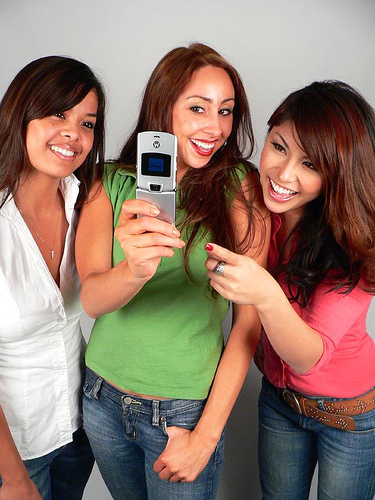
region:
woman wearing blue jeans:
[279, 91, 369, 487]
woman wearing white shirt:
[5, 49, 81, 430]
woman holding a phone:
[105, 45, 233, 432]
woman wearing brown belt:
[276, 87, 368, 495]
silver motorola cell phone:
[133, 131, 185, 225]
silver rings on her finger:
[212, 258, 227, 274]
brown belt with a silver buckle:
[271, 392, 373, 424]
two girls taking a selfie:
[80, 44, 368, 309]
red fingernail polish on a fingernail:
[200, 243, 214, 251]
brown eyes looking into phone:
[190, 100, 239, 119]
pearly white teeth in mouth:
[263, 172, 294, 199]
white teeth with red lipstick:
[42, 137, 83, 160]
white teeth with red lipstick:
[187, 131, 227, 159]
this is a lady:
[243, 72, 373, 498]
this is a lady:
[78, 43, 278, 496]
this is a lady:
[0, 52, 107, 494]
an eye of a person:
[262, 132, 292, 163]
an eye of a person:
[298, 148, 324, 186]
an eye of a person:
[208, 89, 246, 128]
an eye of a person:
[185, 99, 211, 120]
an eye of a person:
[79, 114, 98, 133]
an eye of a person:
[47, 102, 75, 129]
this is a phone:
[115, 122, 201, 279]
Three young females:
[2, 28, 373, 477]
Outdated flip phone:
[130, 123, 177, 226]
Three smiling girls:
[2, 18, 373, 254]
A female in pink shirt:
[202, 68, 372, 415]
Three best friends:
[0, 30, 371, 341]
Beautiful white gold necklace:
[2, 173, 74, 272]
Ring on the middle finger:
[200, 237, 260, 306]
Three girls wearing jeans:
[0, 40, 370, 491]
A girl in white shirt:
[0, 46, 122, 474]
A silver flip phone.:
[137, 130, 178, 226]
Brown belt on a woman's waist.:
[262, 376, 374, 430]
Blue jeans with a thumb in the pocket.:
[79, 365, 225, 498]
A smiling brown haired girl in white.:
[0, 54, 103, 499]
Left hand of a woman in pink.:
[202, 241, 264, 303]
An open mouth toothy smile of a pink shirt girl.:
[266, 175, 299, 202]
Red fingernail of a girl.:
[203, 244, 213, 250]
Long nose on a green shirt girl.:
[203, 108, 222, 137]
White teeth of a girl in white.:
[49, 144, 75, 158]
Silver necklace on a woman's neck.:
[11, 184, 60, 260]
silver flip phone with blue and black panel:
[131, 130, 178, 244]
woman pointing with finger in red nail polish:
[196, 240, 267, 305]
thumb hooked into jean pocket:
[156, 407, 196, 439]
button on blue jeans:
[123, 396, 130, 402]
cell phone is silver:
[137, 130, 177, 228]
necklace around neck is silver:
[5, 181, 64, 259]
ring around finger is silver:
[215, 261, 224, 274]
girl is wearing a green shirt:
[70, 38, 274, 498]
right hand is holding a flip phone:
[113, 125, 188, 278]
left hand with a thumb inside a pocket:
[151, 414, 209, 485]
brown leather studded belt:
[258, 374, 374, 431]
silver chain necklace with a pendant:
[12, 188, 63, 260]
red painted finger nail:
[202, 242, 214, 252]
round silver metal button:
[122, 396, 132, 405]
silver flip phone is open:
[133, 129, 178, 243]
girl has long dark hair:
[110, 38, 270, 306]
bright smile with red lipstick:
[188, 135, 218, 158]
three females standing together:
[1, 53, 373, 497]